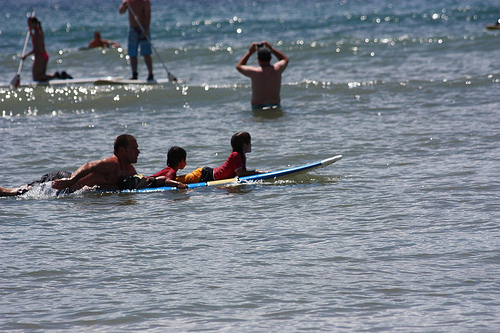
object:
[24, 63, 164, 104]
paddle board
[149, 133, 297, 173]
children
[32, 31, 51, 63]
bikini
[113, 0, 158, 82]
man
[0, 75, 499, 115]
wave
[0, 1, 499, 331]
ocean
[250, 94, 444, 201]
sea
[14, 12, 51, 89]
woman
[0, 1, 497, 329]
water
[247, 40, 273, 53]
hands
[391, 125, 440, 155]
ground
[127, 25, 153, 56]
swim trunks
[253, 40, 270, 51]
camera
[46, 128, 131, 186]
man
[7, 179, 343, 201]
surfboard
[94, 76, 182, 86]
board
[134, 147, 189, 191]
kid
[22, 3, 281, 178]
people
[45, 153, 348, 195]
paddle board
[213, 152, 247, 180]
shirt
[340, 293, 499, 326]
water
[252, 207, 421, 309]
water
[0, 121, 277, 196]
people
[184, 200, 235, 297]
water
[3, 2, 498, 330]
open day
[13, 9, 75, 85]
person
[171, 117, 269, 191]
child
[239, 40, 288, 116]
man